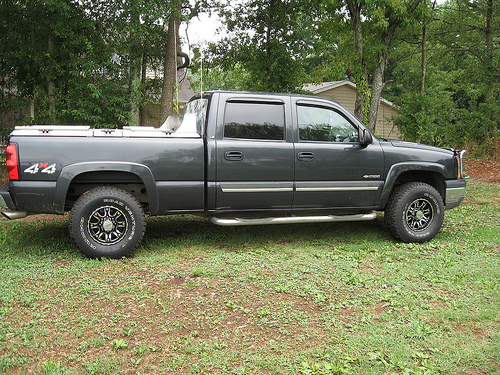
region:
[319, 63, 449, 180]
This is a house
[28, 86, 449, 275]
This is a truck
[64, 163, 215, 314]
This is a wheel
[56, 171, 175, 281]
This is a tire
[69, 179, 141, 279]
The tire is black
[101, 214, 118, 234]
The wheel is silver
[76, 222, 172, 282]
The wheel is metal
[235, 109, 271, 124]
This is a window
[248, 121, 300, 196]
the window is tinted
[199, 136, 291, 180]
This is a handle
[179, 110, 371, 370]
The truck is grey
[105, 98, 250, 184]
This is a window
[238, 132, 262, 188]
This is a handle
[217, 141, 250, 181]
The handle is plastic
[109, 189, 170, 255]
This is a tire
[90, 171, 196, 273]
The tire is black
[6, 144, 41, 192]
This is a light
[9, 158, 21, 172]
The light is red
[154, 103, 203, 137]
This is a trunk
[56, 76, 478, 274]
grey truck with four doors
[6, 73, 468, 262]
grey 4x4 truck with tinted windows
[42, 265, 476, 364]
red dirt with green weeds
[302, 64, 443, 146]
a tannish colored garage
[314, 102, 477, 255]
newer tires on a grey truck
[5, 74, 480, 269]
a grey Chevy 4x4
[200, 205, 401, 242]
a silver running board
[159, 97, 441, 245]
silver running board on a truck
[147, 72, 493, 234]
silver running board on a chevy truck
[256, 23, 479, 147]
trees in a yard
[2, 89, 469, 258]
the truck parked on the grass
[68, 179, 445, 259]
the wheels on the truck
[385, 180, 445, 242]
the front wheel on the truck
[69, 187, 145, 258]
the back wheel on the truck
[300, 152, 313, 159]
the handle on the door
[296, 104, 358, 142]
the window on the door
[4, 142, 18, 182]
the red light in the back of the truck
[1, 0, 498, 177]
the trees behind the truck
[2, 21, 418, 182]
the houses behind the trees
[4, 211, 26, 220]
the muffler under the truck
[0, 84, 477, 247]
a pickup on the grass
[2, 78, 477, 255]
the pickup is black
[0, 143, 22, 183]
a red light on the pickup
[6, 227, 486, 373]
the grass is thin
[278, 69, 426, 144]
a house behind the pickup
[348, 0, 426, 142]
a tree in front of the house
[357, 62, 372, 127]
a vine growing on the tree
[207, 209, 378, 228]
a metal bar under the pickup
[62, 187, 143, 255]
the pickup has a back right wheel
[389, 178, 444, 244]
the pickup has a front right wheel